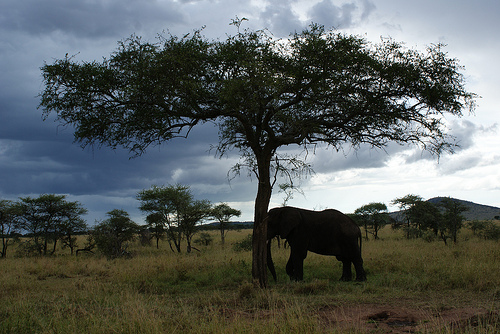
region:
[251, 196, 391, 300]
Large animal near tree.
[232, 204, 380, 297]
Large animal is an elephant.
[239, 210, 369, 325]
Elephant is dark gray in color.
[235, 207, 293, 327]
Elephant is standing near a tree.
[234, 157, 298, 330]
Tree has brown trunk.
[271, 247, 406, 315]
Elephant is standing in green grass.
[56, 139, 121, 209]
Dark clouds in the sky.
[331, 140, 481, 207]
Sky is light on the right.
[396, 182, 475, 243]
Hills in the distance.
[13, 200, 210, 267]
Row of trees in the background.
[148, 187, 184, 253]
a tree in a distance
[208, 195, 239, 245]
a tree in a distance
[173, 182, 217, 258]
a tree in a distance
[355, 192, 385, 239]
a tree in a distance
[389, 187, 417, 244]
a tree in a distance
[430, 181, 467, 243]
a tree in a distance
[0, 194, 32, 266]
a tree in a distance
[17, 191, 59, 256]
a tree in a distance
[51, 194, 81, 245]
a tree in a distance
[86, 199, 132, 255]
a tree in a distance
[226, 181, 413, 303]
Elephant rubbing its head on a tree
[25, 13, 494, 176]
Small leaves on tree protect it from hot climate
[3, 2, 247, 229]
Dark clouds in the sky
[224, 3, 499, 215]
A lighter part of the sky can be seen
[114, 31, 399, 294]
All the branches are up high on this type of tree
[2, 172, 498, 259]
More trees in the background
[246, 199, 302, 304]
Elephants trunk is touching the ground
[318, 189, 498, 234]
Mountain in the background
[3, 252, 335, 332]
Tall grass in the foreground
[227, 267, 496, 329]
An area of dirt in front of the tree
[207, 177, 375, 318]
a elephant standing by a tree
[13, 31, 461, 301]
a elephant in a field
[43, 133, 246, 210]
dark clouds in the sky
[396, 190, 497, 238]
a tall mountain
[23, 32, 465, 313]
a tall wide tree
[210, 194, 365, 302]
a elephant next to a tree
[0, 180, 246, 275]
a row of trees in a field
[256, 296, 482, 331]
red dirt in a field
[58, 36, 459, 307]
a elephant standing under a tree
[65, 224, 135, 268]
a green bush in a field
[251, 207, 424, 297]
The elephant is next to the tree.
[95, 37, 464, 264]
The tree is tall and big.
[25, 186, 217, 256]
Small trees sit in the background.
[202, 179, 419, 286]
The elephant is in the wilderness.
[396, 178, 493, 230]
A hill sit in the background.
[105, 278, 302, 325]
The grass is tall and dry.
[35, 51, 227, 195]
The sky is blue and cloudy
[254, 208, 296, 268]
The elephant trunk is next to the tree.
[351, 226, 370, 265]
The elephant tail is long.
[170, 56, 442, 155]
The tree has a lot of branches